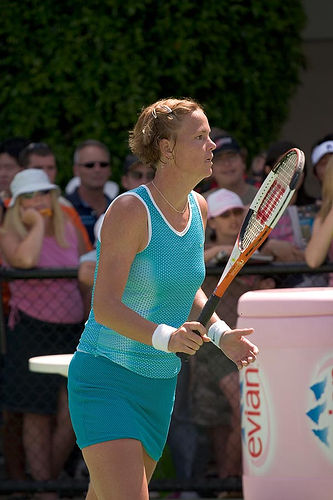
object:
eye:
[196, 132, 204, 139]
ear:
[154, 133, 172, 162]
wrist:
[140, 316, 180, 353]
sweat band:
[144, 319, 241, 353]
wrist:
[149, 320, 180, 361]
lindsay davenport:
[65, 96, 260, 498]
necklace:
[140, 151, 201, 224]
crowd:
[21, 144, 143, 241]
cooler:
[216, 274, 331, 414]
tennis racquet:
[169, 143, 306, 360]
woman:
[60, 84, 234, 487]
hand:
[167, 324, 205, 359]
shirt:
[76, 183, 205, 377]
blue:
[69, 180, 206, 453]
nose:
[206, 137, 217, 152]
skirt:
[67, 350, 179, 462]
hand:
[169, 321, 209, 354]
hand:
[219, 328, 258, 369]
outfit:
[64, 193, 217, 450]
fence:
[7, 255, 327, 431]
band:
[147, 321, 177, 352]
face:
[174, 103, 224, 191]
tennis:
[57, 84, 323, 497]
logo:
[231, 362, 273, 471]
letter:
[253, 177, 286, 224]